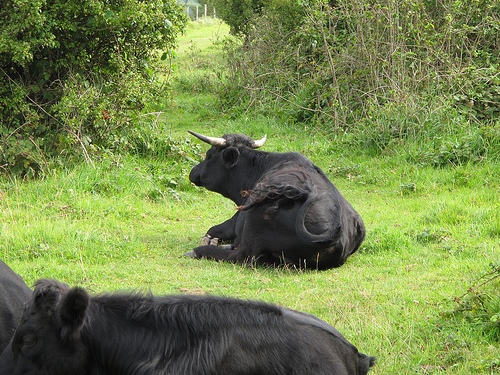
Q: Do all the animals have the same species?
A: Yes, all the animals are bulls.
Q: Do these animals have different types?
A: No, all the animals are bulls.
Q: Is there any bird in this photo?
A: No, there are no birds.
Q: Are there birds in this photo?
A: No, there are no birds.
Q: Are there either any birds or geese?
A: No, there are no birds or geese.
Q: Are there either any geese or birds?
A: No, there are no birds or geese.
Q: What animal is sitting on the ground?
A: The bull is sitting on the ground.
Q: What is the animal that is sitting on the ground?
A: The animal is a bull.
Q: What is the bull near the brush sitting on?
A: The bull is sitting on the ground.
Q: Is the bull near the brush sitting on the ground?
A: Yes, the bull is sitting on the ground.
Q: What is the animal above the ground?
A: The animal is a bull.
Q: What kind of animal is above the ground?
A: The animal is a bull.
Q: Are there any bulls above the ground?
A: Yes, there is a bull above the ground.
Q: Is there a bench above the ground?
A: No, there is a bull above the ground.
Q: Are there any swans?
A: No, there are no swans.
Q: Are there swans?
A: No, there are no swans.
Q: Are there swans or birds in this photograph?
A: No, there are no swans or birds.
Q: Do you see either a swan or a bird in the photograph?
A: No, there are no swans or birds.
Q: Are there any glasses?
A: No, there are no glasses.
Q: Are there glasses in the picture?
A: No, there are no glasses.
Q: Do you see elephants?
A: No, there are no elephants.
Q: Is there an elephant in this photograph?
A: No, there are no elephants.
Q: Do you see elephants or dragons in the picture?
A: No, there are no elephants or dragons.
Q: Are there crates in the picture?
A: No, there are no crates.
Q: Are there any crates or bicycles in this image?
A: No, there are no crates or bicycles.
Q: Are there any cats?
A: No, there are no cats.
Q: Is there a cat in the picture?
A: No, there are no cats.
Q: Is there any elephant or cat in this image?
A: No, there are no cats or elephants.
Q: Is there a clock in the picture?
A: No, there are no clocks.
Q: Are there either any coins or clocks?
A: No, there are no clocks or coins.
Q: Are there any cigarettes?
A: No, there are no cigarettes.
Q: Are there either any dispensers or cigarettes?
A: No, there are no cigarettes or dispensers.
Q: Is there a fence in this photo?
A: Yes, there is a fence.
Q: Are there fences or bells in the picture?
A: Yes, there is a fence.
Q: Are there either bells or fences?
A: Yes, there is a fence.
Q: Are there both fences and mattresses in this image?
A: No, there is a fence but no mattresses.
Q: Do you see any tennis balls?
A: No, there are no tennis balls.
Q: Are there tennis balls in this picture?
A: No, there are no tennis balls.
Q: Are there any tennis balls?
A: No, there are no tennis balls.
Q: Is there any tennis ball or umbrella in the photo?
A: No, there are no tennis balls or umbrellas.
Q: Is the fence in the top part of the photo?
A: Yes, the fence is in the top of the image.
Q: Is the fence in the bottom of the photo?
A: No, the fence is in the top of the image.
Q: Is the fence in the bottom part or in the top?
A: The fence is in the top of the image.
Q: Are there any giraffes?
A: No, there are no giraffes.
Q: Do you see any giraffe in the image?
A: No, there are no giraffes.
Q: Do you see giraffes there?
A: No, there are no giraffes.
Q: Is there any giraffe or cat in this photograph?
A: No, there are no giraffes or cats.